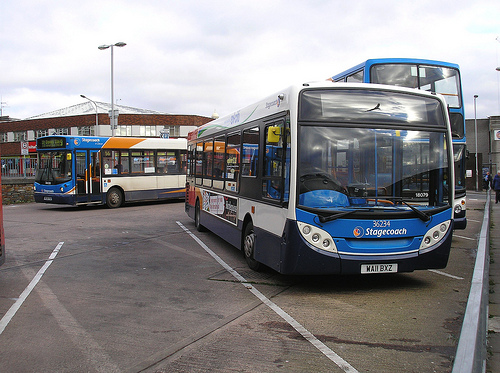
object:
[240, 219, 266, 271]
wheel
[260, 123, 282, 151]
mirror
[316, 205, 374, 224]
windshield wiper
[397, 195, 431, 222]
windshield wiper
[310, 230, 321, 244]
light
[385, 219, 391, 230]
number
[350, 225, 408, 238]
manufacturer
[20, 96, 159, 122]
roof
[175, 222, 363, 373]
line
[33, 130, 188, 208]
bus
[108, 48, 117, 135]
metal pole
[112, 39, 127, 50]
fixtures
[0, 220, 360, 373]
parking slot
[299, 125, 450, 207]
window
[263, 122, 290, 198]
window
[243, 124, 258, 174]
window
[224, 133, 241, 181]
window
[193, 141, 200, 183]
window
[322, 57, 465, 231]
bus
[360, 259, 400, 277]
license plate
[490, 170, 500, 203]
people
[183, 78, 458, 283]
bus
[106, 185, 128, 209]
wheel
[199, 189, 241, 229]
advertisement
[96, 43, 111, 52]
light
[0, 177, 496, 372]
parking lot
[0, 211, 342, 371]
space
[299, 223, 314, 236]
headlight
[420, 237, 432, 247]
headlight